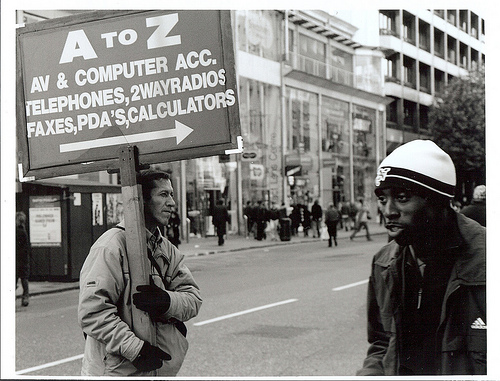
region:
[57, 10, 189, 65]
beginning and end of the alphabet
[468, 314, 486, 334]
small white ADIDAS logo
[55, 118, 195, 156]
a white arrow pointing to the right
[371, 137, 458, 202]
white hat with black stripes and a patch on the front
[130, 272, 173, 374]
two black gloves holding on to a wooden post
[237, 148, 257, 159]
Mastercard logo in the background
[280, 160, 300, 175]
a sign for Subway in the background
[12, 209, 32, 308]
a woman standing by the bus stop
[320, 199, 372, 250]
two people standing in the street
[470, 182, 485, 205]
a man with white hair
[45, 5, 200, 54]
A to Z in white on a sign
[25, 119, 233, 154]
a white arrow on a sign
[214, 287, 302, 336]
a white line on a street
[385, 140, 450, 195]
a black and white hoodie on a man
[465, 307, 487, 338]
the adidas symbol on a man's jacket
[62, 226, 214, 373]
a light jacket on a man holding a sign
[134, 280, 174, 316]
a black glove on a man's left hand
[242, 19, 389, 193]
a large glass front of a building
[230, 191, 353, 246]
people congregating in front of a building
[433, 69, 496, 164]
a tree in front of a building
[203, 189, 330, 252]
Crowd of people near store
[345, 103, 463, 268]
Dark skinned man wearing a beanie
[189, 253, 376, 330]
Paved road white lines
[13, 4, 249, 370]
Man holding sign for electronics business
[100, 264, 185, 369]
Black gloves being worn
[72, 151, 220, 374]
Man waring a thick poofy jacket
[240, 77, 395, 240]
Businesses with glass store fronts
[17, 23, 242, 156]
Sign with arrow pointing towards business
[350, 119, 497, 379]
Man wearing addidas jacket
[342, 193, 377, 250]
Person walking across the street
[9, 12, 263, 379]
man holding sign in the street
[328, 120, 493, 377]
man walking on the street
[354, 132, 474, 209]
knit hat on a man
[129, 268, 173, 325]
gloves on man's left hand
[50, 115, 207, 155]
arrow on a sign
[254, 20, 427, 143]
buildings along a city street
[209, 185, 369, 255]
pedestrians on a side walk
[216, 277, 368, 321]
white painted lines in a road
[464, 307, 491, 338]
adidas logo on a jacket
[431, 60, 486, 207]
tree on side of the street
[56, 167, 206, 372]
man in a light coat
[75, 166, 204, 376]
man in dark heavy gloves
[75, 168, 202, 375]
man with grimace on his face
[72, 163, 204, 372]
man with a short haircut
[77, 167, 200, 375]
man carrying a sign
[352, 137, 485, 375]
man with sock hat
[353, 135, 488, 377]
man with his mouth open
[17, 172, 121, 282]
small building on curb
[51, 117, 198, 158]
long arrow pointing to the right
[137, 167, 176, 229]
head of man carrying sign